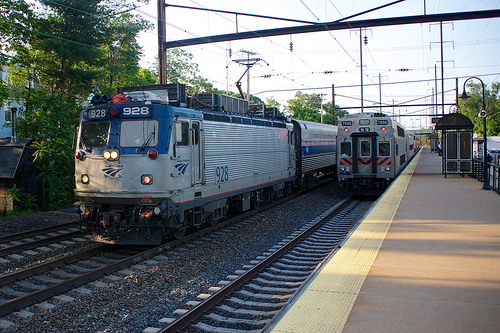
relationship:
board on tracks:
[228, 261, 308, 292] [145, 190, 382, 332]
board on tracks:
[228, 261, 308, 292] [0, 195, 371, 331]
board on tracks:
[177, 294, 284, 322] [0, 195, 371, 331]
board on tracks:
[177, 294, 284, 322] [145, 190, 382, 332]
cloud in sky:
[187, 1, 345, 67] [131, 0, 484, 129]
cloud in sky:
[316, 41, 412, 83] [131, 0, 484, 129]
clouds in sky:
[2, 1, 499, 128] [1, 2, 498, 138]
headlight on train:
[140, 171, 152, 184] [66, 64, 314, 259]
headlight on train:
[79, 175, 90, 183] [66, 64, 314, 259]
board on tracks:
[1, 262, 114, 328] [16, 190, 411, 332]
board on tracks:
[1, 262, 114, 328] [4, 179, 379, 331]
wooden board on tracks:
[42, 262, 90, 274] [14, 245, 118, 297]